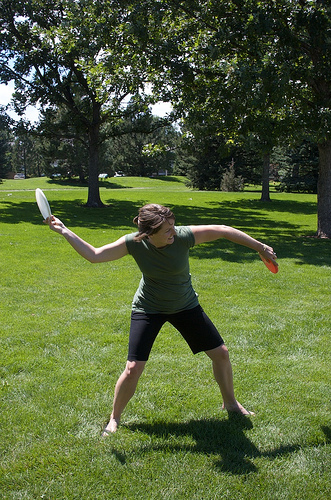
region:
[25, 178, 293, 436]
woman standing on grass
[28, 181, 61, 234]
white Frisbee in hand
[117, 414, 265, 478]
shadow of woman in grass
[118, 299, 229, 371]
tight black shorts on woman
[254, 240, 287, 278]
orange Frisbee in hand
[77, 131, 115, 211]
trunk of tree in grass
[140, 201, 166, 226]
light reflection in hair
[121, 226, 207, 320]
short sleeve green shirt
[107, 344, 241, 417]
bare legs on woman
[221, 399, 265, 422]
bare foot in grass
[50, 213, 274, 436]
a woman standing in the park on a sunny day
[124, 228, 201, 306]
the green tank top the woman is wearing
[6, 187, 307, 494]
a lot of lush green grass in the park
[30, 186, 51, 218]
the white frisbee in the woman's right hand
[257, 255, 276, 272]
the red frisbee in the woman's hand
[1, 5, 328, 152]
the green leaves of the trees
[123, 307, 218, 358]
the black shorts the woman is wearing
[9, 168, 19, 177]
a car in the background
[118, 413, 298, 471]
the shadow of the woman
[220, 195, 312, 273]
the shadows from the trees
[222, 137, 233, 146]
a green tree leaf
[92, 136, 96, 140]
a green tree leaf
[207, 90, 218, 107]
a green tree leaf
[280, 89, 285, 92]
a green tree leaf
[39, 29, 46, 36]
a green tree leaf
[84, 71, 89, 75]
a green tree leaf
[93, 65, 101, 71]
a green tree leaf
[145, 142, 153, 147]
a green tree leaf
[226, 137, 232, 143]
a green tree leaf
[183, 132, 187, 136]
a green tree leaf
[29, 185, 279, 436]
a woman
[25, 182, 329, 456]
a woman at a park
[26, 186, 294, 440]
a woman holding a frisbee in each hand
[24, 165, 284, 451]
the woman has a white frisbee in her right hand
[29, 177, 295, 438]
the woman is throwing the white frisbee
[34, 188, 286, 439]
the woman has an orange frisbee in her left hand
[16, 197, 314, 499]
the grass is green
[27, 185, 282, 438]
the woman is wearing a green shirt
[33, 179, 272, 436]
the woman is wearing black shorts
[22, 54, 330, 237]
trees are in the park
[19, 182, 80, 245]
a white frisbee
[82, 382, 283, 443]
flipflops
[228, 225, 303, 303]
a red frisbee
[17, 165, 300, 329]
a woman holding a white frisbee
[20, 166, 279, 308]
a woman holding a red frisbee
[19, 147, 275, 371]
a woman with brown hair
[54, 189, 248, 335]
a woman wearing a pony tail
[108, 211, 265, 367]
a woman wearing black shorts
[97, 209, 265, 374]
a woman wearing a green shirt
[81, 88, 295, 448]
a woman wearing flip flops